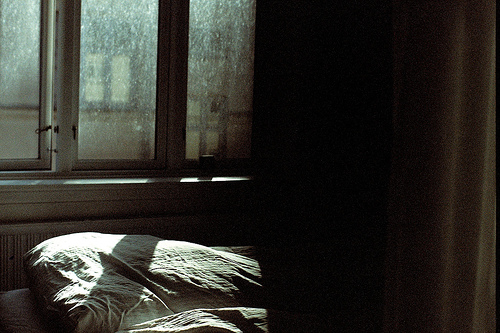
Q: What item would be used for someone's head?
A: Pillow.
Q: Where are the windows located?
A: Above bed.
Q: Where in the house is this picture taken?
A: Bedroom.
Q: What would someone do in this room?
A: Sleep.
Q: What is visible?
A: Pillow.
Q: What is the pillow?
A: Visible.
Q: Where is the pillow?
A: On the bed.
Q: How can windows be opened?
A: From inside.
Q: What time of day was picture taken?
A: Morning.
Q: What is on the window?
A: Dirt.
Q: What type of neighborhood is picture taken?
A: Urban.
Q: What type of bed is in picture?
A: Twin.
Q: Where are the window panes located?
A: Above the bed.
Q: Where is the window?
A: Behind bed.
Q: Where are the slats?
A: On wall.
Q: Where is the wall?
A: In bedroom.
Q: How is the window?
A: Dirty.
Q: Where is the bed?
A: Below window.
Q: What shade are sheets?
A: White.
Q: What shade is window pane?
A: White.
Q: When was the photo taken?
A: Night time.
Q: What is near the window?
A: Pillow.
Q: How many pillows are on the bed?
A: 1.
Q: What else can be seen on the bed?
A: Sheet.